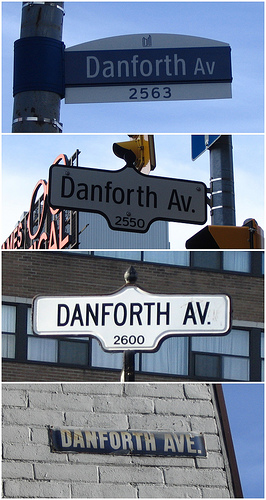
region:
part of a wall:
[175, 480, 182, 487]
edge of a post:
[79, 435, 81, 437]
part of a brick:
[86, 468, 91, 479]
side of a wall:
[224, 423, 231, 443]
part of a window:
[208, 351, 214, 358]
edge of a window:
[44, 353, 46, 358]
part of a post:
[130, 345, 137, 363]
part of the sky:
[235, 406, 245, 427]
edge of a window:
[64, 356, 70, 370]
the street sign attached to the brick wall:
[45, 426, 208, 459]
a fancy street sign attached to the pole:
[30, 267, 230, 380]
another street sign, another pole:
[41, 158, 215, 240]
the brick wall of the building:
[2, 383, 240, 498]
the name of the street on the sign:
[81, 54, 215, 80]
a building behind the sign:
[5, 254, 264, 383]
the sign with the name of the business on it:
[4, 155, 73, 246]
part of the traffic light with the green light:
[112, 135, 156, 168]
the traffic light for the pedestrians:
[183, 219, 264, 252]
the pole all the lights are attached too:
[186, 136, 239, 243]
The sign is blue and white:
[58, 46, 230, 83]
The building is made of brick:
[52, 388, 177, 423]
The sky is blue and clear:
[229, 401, 265, 454]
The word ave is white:
[155, 430, 220, 456]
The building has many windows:
[1, 304, 259, 384]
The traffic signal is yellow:
[106, 137, 160, 170]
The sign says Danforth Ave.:
[49, 419, 225, 471]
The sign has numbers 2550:
[104, 208, 154, 235]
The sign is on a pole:
[2, 22, 95, 119]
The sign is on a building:
[43, 414, 243, 478]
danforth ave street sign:
[43, 153, 220, 238]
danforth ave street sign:
[41, 423, 213, 461]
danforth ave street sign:
[26, 285, 242, 353]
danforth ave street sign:
[66, 35, 246, 105]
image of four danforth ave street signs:
[5, 12, 241, 497]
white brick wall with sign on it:
[7, 390, 183, 497]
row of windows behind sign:
[12, 299, 263, 378]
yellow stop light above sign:
[109, 142, 170, 181]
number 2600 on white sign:
[107, 333, 164, 344]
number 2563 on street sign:
[122, 81, 180, 103]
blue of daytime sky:
[60, 3, 264, 129]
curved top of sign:
[65, 32, 231, 51]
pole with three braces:
[11, 2, 66, 132]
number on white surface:
[63, 84, 234, 106]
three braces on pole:
[207, 147, 234, 225]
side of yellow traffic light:
[115, 136, 149, 167]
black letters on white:
[53, 297, 213, 327]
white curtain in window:
[190, 327, 250, 378]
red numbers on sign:
[0, 153, 71, 249]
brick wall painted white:
[6, 385, 228, 495]